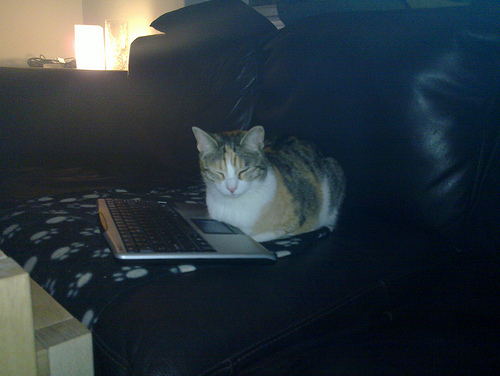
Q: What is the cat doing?
A: Sleeping.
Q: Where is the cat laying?
A: Couch.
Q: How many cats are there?
A: One.